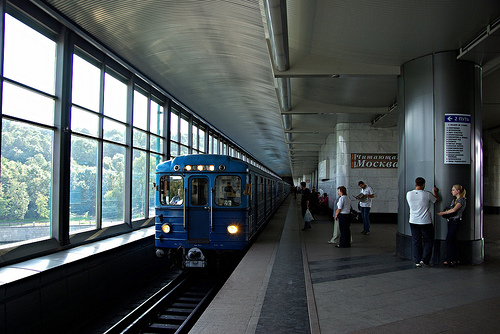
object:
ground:
[319, 120, 344, 138]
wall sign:
[443, 114, 471, 165]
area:
[2, 1, 497, 332]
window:
[67, 44, 102, 237]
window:
[100, 63, 133, 231]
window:
[129, 81, 148, 222]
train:
[154, 154, 293, 272]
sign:
[350, 152, 398, 169]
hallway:
[347, 69, 497, 331]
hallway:
[267, 122, 334, 223]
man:
[404, 176, 440, 268]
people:
[333, 185, 352, 248]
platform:
[189, 190, 499, 333]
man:
[298, 181, 313, 231]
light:
[227, 224, 239, 234]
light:
[160, 221, 171, 233]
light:
[207, 164, 215, 171]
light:
[195, 163, 204, 170]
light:
[183, 163, 192, 171]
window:
[0, 7, 66, 267]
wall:
[398, 57, 434, 257]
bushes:
[0, 153, 156, 224]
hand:
[431, 185, 440, 196]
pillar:
[395, 50, 485, 265]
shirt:
[406, 189, 438, 224]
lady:
[436, 184, 467, 266]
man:
[351, 180, 376, 235]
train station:
[0, 0, 498, 333]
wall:
[350, 123, 402, 223]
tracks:
[103, 269, 231, 333]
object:
[350, 192, 366, 201]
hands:
[364, 193, 369, 197]